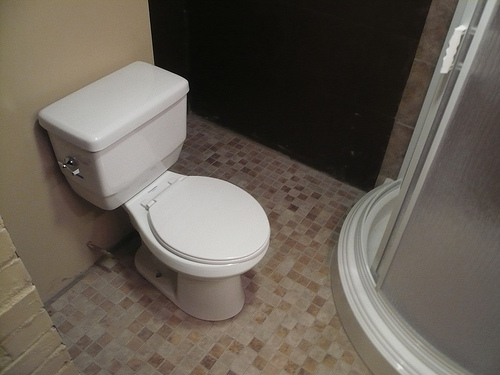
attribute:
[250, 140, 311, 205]
floor — tiled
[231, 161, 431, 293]
floor — dark, light, brown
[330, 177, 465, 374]
shower base — white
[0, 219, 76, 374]
wall — brick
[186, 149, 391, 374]
tiles — small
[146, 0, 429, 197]
wall — dark, ominous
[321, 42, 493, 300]
shower — white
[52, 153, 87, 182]
handle — toilet, silver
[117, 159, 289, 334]
toilet — white, ceramic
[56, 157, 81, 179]
toilet handle — shiny, grey, metal